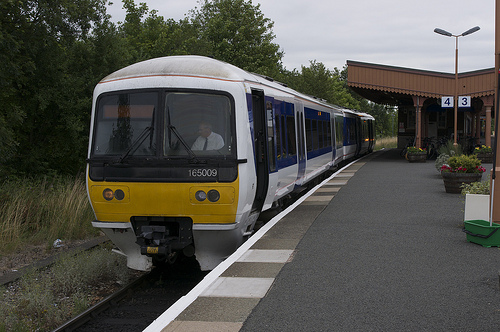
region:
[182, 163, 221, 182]
165009 is the number of the train.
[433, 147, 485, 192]
Planter on the platform that is growing red flowers.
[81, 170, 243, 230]
Portion on the front of the train painted yellow.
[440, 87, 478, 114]
Pole that has two numbers attached.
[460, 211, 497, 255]
Green bucket with a black handle.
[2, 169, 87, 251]
Tall grasses growing alongside the tracks.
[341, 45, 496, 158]
Covered portion of the train station.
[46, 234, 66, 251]
Piece of litter on the ground next to the tracks.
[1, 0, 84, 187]
deciduous tree next to grass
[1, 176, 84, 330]
railroad tracks with grass and weeds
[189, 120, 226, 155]
train engineer in the cab of the engine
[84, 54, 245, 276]
front of a passenger train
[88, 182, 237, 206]
headlights of a passenger train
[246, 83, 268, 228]
open door of a train engine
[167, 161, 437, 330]
empty platform at a train station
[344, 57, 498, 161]
train station with passenger cars at the platform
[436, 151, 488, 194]
ornamental planter with pink flowers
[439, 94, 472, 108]
track number signs at a station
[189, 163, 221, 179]
number of the train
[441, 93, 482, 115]
numbers of the train station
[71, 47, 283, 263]
front of the train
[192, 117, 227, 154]
driver of the train with a white shirt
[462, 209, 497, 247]
green recycling bin on the road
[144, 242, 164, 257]
yellow light on the train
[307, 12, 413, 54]
cloudy sky in the distance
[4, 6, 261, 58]
trees in the distance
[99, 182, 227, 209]
headlights on the front of the train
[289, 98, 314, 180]
doors to enter the train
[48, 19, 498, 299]
this is a train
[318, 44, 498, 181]
a train platform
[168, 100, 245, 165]
driver of the train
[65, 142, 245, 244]
yellow trim on the train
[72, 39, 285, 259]
the train is white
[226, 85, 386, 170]
windows on the train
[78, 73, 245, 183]
front windows on the train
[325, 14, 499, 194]
this is a train station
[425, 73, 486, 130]
number signs on the building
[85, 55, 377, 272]
a train at the station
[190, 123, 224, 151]
driver of the train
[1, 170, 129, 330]
weeds by the tracks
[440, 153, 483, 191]
flowers in a flower pot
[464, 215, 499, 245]
the bucket is green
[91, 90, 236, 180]
front window of train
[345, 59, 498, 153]
the building is brown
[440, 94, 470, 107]
numbered signs on pole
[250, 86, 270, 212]
door of the train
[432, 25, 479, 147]
light pole at train station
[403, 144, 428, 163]
black pot of plants and yellow flowers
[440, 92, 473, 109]
white number signs on brown light pole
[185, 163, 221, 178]
white identification numbers on the white train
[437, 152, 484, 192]
large wood basin of plants and flowers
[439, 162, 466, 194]
red flowers in a large pot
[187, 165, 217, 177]
white numbers on a train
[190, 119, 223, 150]
person inside the train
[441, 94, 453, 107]
white sign that says 4 in black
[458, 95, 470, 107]
white sign that says 3 in black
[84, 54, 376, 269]
white train with blue doors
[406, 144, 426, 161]
flower pot with red and yellow flowers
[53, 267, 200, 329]
set of train tracks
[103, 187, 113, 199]
round orange light on the train